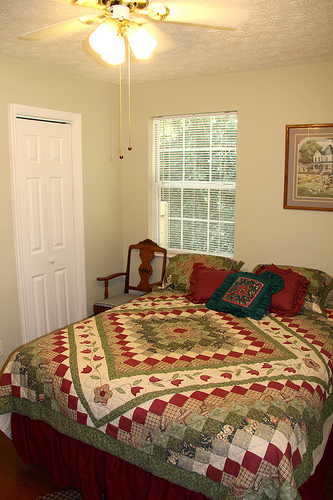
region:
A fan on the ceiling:
[12, 1, 252, 66]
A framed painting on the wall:
[280, 118, 331, 216]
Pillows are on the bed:
[154, 249, 330, 325]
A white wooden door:
[7, 99, 90, 347]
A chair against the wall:
[90, 231, 171, 317]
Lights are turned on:
[84, 19, 164, 68]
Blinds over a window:
[150, 108, 239, 259]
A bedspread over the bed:
[1, 289, 331, 496]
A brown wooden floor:
[0, 423, 62, 499]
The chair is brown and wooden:
[91, 236, 170, 318]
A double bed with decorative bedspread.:
[0, 289, 332, 498]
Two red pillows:
[186, 262, 309, 318]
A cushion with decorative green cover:
[205, 271, 282, 322]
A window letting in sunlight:
[148, 110, 237, 258]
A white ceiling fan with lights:
[18, 0, 249, 54]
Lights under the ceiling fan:
[88, 5, 156, 65]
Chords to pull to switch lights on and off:
[119, 46, 131, 159]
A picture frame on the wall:
[280, 122, 331, 210]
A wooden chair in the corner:
[92, 239, 166, 315]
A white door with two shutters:
[7, 103, 86, 345]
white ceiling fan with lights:
[18, 1, 246, 40]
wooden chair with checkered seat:
[93, 237, 166, 312]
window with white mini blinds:
[152, 119, 233, 255]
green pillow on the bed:
[211, 269, 277, 317]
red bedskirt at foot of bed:
[10, 412, 205, 493]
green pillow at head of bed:
[161, 259, 241, 290]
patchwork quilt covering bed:
[7, 270, 323, 498]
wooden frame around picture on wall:
[283, 122, 330, 209]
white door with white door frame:
[7, 103, 88, 340]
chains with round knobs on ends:
[118, 56, 134, 161]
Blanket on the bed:
[148, 299, 276, 446]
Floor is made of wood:
[16, 463, 42, 496]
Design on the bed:
[146, 379, 254, 487]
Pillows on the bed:
[178, 255, 318, 341]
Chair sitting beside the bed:
[112, 232, 192, 349]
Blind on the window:
[143, 109, 239, 251]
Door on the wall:
[13, 116, 102, 351]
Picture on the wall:
[280, 124, 331, 210]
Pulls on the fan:
[110, 120, 142, 168]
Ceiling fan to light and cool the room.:
[14, 3, 193, 62]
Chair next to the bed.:
[91, 233, 177, 318]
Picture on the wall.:
[264, 159, 329, 215]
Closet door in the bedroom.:
[7, 101, 91, 344]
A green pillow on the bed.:
[206, 262, 285, 321]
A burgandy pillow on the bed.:
[185, 255, 239, 305]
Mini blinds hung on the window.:
[155, 109, 236, 251]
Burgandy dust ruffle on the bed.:
[13, 422, 117, 496]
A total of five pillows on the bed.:
[137, 238, 324, 312]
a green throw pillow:
[204, 269, 281, 319]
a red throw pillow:
[185, 262, 238, 304]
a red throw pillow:
[255, 263, 309, 316]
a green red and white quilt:
[2, 286, 331, 498]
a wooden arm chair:
[93, 237, 167, 313]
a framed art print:
[281, 123, 331, 211]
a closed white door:
[8, 103, 87, 347]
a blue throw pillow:
[207, 268, 278, 320]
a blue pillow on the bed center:
[208, 269, 275, 320]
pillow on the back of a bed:
[172, 248, 325, 319]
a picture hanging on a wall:
[282, 122, 330, 216]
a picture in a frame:
[283, 122, 331, 211]